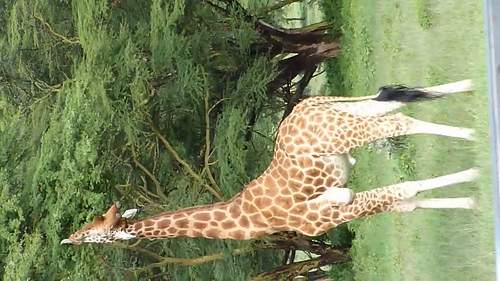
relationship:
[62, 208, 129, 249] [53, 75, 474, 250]
head of giraffe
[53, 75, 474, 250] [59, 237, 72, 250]
giraffe sticking out h tongue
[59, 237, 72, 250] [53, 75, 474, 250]
tongue of giraffe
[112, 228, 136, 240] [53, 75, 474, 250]
ear of giraffe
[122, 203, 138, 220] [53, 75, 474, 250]
ear of giraffe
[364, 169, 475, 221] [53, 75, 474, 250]
front legs of giraffe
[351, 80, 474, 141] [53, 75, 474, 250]
back legs of giraffe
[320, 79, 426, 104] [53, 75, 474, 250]
tail of giraffe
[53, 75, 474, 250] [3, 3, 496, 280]
giraffe in wild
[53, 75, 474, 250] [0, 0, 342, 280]
giraffe eating from a branches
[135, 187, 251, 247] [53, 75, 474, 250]
neck of giraffe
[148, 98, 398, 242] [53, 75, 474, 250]
spots on giraffe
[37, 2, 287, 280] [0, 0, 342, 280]
branches on branches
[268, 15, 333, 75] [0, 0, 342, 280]
trunk of branches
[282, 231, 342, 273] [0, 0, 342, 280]
trunk of branches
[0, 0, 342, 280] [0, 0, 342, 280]
branches in branches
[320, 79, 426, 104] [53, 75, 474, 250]
tail on giraffe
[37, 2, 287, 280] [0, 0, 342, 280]
branches of branches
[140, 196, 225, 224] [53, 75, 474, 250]
mane of giraffe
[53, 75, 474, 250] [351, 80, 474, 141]
giraffe has back legs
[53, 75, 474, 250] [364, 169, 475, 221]
giraffe has front legs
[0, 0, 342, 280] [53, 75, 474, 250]
branches behind giraffe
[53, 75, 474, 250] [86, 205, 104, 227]
giraffe has ossicles